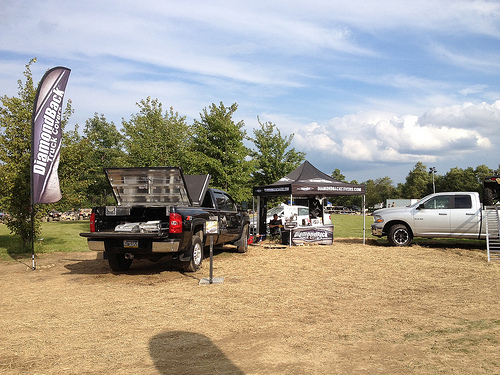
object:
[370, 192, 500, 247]
car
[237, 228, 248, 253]
front wheel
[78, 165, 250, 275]
truck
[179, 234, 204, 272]
back wheel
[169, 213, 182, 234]
back light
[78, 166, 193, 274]
back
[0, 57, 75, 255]
tree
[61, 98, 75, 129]
branch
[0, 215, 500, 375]
field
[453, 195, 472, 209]
window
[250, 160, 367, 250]
tent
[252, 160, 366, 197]
upper part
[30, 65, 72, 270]
banner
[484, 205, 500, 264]
ladder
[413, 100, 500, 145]
cloud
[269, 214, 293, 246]
person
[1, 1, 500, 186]
sky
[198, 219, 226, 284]
sign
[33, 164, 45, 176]
letter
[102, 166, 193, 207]
cover